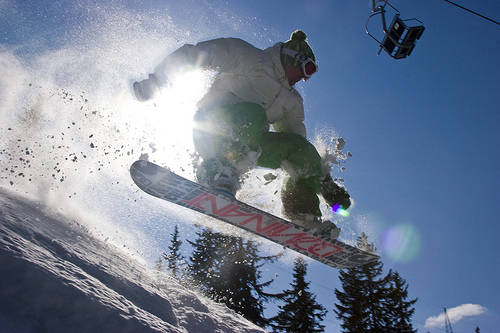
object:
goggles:
[281, 48, 318, 83]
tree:
[332, 232, 421, 332]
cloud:
[420, 302, 491, 332]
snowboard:
[129, 157, 380, 270]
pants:
[192, 102, 325, 216]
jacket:
[154, 37, 308, 138]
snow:
[2, 2, 348, 256]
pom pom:
[289, 28, 308, 41]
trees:
[267, 255, 328, 333]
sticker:
[393, 20, 400, 32]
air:
[2, 4, 121, 90]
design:
[181, 191, 344, 257]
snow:
[2, 187, 269, 333]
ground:
[1, 186, 299, 332]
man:
[132, 30, 352, 239]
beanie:
[280, 29, 317, 66]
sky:
[2, 2, 127, 151]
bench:
[375, 16, 424, 60]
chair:
[381, 17, 426, 60]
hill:
[0, 183, 269, 333]